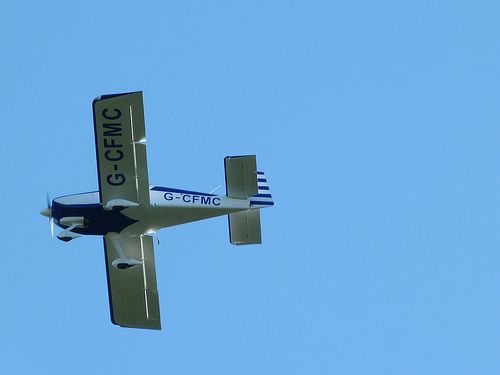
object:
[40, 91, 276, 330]
plane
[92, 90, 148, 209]
wing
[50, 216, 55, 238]
propeller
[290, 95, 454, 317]
air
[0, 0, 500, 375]
sky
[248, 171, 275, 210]
tail